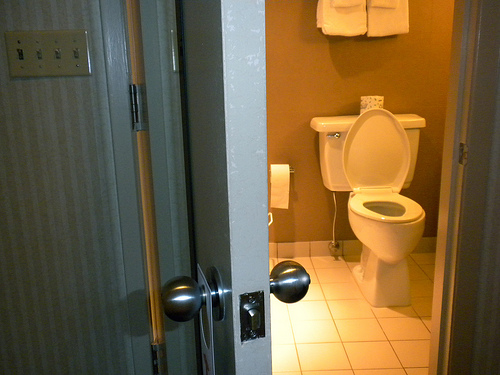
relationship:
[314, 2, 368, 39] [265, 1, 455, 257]
towel on wall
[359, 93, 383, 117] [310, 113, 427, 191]
toilet paper on tank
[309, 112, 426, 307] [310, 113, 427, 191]
toilet has tank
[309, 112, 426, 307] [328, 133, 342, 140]
toilet has lever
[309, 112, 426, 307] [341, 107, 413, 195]
toilet has lid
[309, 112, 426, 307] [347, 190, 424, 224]
toilet has seat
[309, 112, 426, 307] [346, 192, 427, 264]
toilet has bowl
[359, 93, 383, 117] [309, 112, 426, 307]
toilet paper on top of toilet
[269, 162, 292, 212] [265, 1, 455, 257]
toilet paper on wall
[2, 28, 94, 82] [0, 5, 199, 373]
light switch on wall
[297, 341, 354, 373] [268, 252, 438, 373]
tile on floor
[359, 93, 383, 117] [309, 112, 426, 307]
toilet paper on toilet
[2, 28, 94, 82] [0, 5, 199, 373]
light switches on wall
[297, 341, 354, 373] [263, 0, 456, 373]
tile in restroom